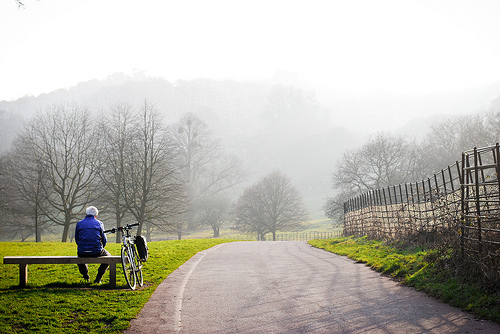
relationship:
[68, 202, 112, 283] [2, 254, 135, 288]
man on bench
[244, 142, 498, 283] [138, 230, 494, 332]
fence near road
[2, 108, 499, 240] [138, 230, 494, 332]
trees near road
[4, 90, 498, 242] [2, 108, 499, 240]
mountains behind trees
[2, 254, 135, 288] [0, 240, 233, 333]
bench on grass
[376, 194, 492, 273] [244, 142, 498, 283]
vines on fence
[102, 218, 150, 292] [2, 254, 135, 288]
bike leaning on bench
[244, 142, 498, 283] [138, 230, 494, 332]
fence along road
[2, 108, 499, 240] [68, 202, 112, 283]
trees in front of man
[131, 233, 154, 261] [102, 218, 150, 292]
bag on bike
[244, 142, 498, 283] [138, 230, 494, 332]
fence opposite road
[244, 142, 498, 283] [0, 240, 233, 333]
fence opposite grass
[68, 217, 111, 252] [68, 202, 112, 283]
coat on man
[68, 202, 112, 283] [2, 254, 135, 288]
man sitting on bench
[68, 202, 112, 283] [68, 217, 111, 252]
man wearing coat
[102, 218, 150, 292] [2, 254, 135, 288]
bike on bench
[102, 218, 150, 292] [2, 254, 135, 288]
bike near bench